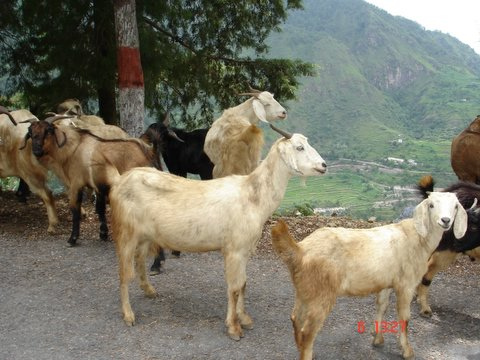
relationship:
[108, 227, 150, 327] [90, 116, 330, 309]
leg of a goat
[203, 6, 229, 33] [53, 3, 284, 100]
leaf growing on plant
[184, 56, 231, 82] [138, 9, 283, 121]
leaf growing on plant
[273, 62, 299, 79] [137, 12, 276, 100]
leaf growing on plant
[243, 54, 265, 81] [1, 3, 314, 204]
leaf on plant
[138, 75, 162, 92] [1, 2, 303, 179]
leaf on plant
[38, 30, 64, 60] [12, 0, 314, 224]
leaf on plant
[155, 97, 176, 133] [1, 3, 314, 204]
leaf on plant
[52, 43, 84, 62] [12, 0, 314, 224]
leaf on plant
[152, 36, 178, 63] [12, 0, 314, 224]
leaf on plant